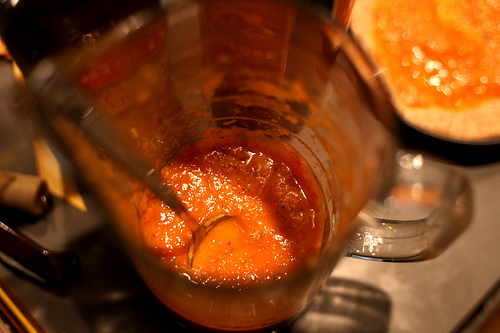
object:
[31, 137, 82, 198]
objects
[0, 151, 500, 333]
counter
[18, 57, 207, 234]
handle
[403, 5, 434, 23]
orange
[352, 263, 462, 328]
countertop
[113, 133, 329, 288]
liquid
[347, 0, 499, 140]
food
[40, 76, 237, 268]
spoon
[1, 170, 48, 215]
brown handle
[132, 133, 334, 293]
rings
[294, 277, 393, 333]
shadow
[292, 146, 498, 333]
metal surface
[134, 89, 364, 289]
dish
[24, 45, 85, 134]
spout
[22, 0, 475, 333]
container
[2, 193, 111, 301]
object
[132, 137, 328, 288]
food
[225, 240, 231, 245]
speck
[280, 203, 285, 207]
speck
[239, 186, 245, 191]
speck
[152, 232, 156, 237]
speck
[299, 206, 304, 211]
speck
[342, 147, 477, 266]
handle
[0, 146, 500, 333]
surface